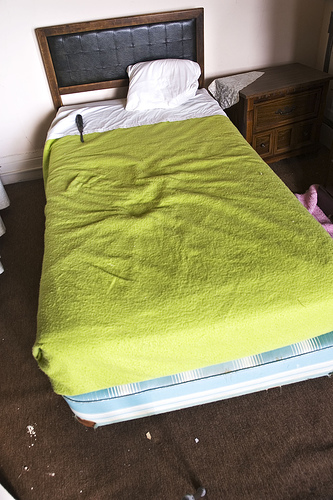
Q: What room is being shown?
A: Bedroom.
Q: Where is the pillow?
A: Head of the bed.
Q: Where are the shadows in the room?
A: Top right corner.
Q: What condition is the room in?
A: Messy.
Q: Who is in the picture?
A: No one.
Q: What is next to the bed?
A: Nightstand.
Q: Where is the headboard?
A: At the top of the bed.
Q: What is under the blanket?
A: Mattress.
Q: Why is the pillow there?
A: To lay on.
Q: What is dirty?
A: The floor.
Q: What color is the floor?
A: Brown.